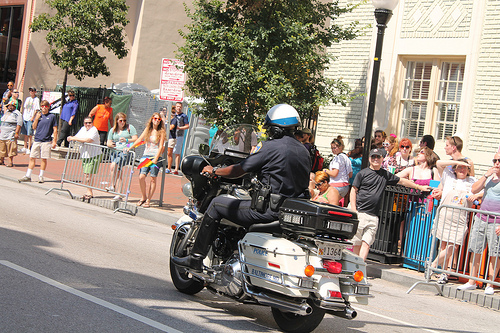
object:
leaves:
[79, 38, 84, 41]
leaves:
[88, 12, 91, 19]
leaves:
[75, 32, 80, 42]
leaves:
[97, 5, 100, 10]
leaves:
[66, 7, 68, 10]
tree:
[24, 0, 131, 97]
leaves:
[269, 65, 271, 70]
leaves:
[231, 56, 235, 65]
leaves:
[213, 38, 220, 48]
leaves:
[287, 35, 292, 41]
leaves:
[231, 83, 236, 89]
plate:
[317, 243, 342, 260]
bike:
[170, 144, 368, 333]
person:
[455, 152, 499, 295]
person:
[170, 102, 190, 178]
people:
[103, 112, 138, 203]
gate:
[63, 139, 135, 201]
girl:
[322, 135, 353, 209]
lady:
[432, 160, 471, 279]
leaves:
[179, 3, 365, 108]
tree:
[181, 0, 367, 151]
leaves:
[207, 16, 269, 63]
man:
[86, 96, 113, 149]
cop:
[169, 103, 311, 272]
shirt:
[93, 104, 112, 132]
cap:
[369, 148, 384, 156]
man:
[341, 147, 431, 280]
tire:
[168, 227, 205, 296]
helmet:
[262, 104, 302, 140]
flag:
[137, 157, 159, 170]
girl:
[121, 112, 167, 208]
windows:
[389, 54, 466, 139]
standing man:
[18, 100, 59, 184]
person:
[387, 138, 415, 171]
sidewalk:
[1, 142, 498, 306]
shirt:
[351, 166, 400, 214]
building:
[313, 1, 500, 177]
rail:
[368, 184, 500, 286]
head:
[260, 104, 302, 136]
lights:
[303, 265, 315, 277]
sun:
[14, 18, 488, 195]